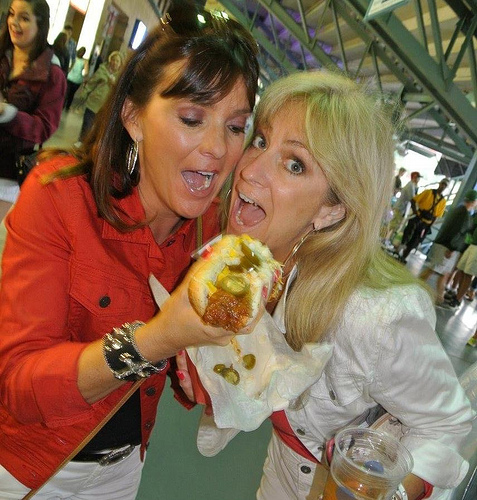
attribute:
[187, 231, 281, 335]
dog — chili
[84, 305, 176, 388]
bracelet — silver, metal, black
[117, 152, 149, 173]
earring — silver, hoop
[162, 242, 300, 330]
food — hot dog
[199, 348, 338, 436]
paper — white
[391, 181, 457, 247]
shirt — yellow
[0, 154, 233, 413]
jacket — red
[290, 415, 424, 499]
beer — cup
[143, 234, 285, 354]
hot dog — fallen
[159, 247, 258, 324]
dog — chilli, chili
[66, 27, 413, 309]
women — wearing, sharing, blonde, holding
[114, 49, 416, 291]
woman — background, holding, wearing, brunette, blonde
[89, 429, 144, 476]
buckle — metal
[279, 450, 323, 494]
button — pant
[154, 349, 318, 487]
wrapper — jalapeno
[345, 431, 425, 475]
cup — clear, plastic, beer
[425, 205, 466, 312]
man — wearing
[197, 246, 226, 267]
nail — pink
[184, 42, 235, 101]
hair — dark